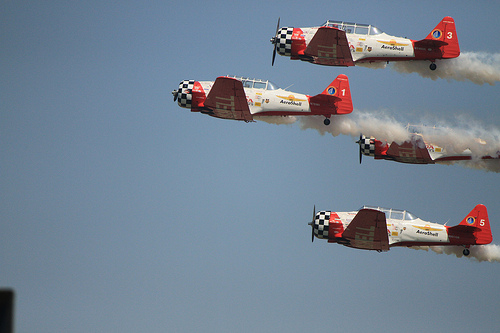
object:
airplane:
[270, 16, 460, 71]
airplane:
[308, 203, 492, 256]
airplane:
[355, 131, 500, 165]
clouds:
[0, 0, 500, 333]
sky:
[5, 3, 495, 327]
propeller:
[172, 89, 182, 102]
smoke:
[420, 113, 500, 174]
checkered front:
[172, 80, 195, 109]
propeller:
[308, 204, 315, 242]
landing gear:
[463, 245, 470, 256]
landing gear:
[323, 114, 331, 125]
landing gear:
[428, 59, 437, 70]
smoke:
[299, 112, 410, 145]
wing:
[303, 26, 355, 67]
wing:
[203, 76, 253, 120]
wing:
[386, 133, 433, 163]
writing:
[216, 101, 234, 106]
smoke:
[442, 245, 500, 263]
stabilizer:
[448, 225, 482, 234]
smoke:
[394, 51, 500, 85]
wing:
[342, 208, 390, 245]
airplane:
[172, 74, 354, 126]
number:
[356, 225, 376, 231]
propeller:
[270, 16, 280, 66]